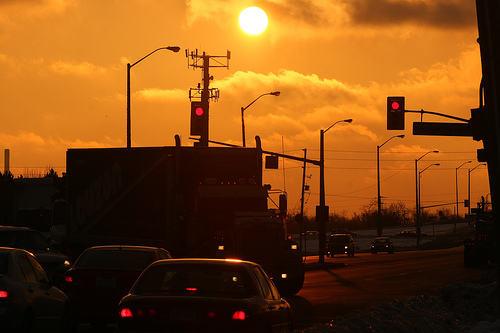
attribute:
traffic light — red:
[370, 71, 405, 155]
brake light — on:
[117, 306, 137, 322]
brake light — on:
[226, 309, 246, 324]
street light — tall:
[373, 133, 407, 243]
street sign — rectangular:
[412, 119, 478, 138]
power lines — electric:
[290, 143, 441, 172]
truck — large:
[64, 138, 308, 298]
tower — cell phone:
[183, 46, 233, 149]